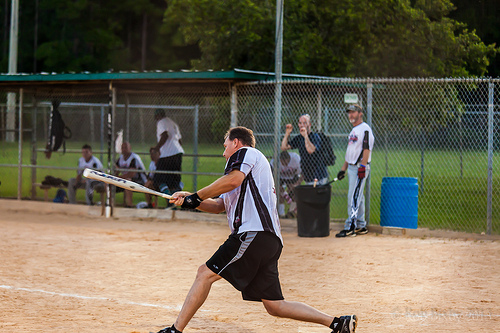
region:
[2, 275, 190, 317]
white chalk line on field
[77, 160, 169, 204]
aluminum bat in hand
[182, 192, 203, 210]
black wristband on arm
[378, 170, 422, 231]
blue trashcan behind fence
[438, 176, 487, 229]
green grass behind the fence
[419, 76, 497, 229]
silver and grey fence on grass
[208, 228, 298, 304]
black shorts on man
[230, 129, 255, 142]
the man's brown hair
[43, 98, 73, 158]
black bag hanging on fence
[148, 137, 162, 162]
glove in man's hand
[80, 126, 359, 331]
Man swinging baseball bat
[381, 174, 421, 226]
Blue garbage pail behind the fence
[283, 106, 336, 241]
Man watching from behind the fence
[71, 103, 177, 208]
Players in the dugouot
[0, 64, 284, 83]
Green roof over the dugout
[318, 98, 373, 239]
Player holding a bat in each hands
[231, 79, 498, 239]
Steel fence at edge of field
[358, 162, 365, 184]
Batting glove on man's hand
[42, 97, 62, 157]
Jacket hanging from fence in dugout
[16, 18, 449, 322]
a baseball player at bat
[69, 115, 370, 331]
he is using batter form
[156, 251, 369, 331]
his legs are spread apart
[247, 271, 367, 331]
his back leg is extended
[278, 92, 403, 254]
these guys are watching the action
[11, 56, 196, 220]
these guys are sitting under shelter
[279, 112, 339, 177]
this guy has on a backpack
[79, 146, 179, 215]
a wooden baseball bat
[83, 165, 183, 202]
Bat being swung by a person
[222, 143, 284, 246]
A white and black shirt on a man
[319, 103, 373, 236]
A man picking up a bat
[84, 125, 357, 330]
A man swinging a bat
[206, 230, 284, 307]
Black shorts on a man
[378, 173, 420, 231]
A large blue barrel behind a wire fence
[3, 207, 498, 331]
Brown dirt on a baseball field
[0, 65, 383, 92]
Green awning over a bullpen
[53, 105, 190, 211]
Men standing under an awning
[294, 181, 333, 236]
Black, plastic bin full of bats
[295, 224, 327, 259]
part of a ground